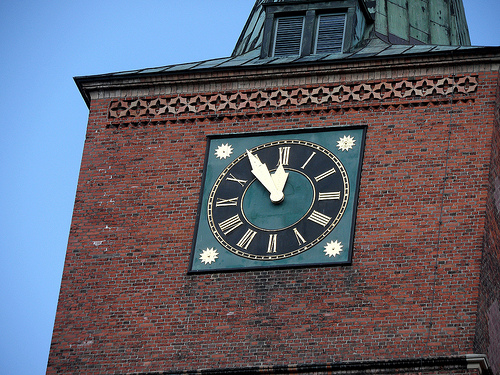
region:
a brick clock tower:
[33, 0, 493, 365]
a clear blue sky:
[1, 0, 54, 313]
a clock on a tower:
[194, 125, 354, 267]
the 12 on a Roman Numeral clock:
[273, 141, 292, 166]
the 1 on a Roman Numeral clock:
[299, 144, 318, 172]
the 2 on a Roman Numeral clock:
[311, 160, 337, 182]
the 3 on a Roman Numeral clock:
[316, 187, 343, 203]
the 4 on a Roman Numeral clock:
[305, 202, 331, 228]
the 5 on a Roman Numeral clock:
[287, 225, 303, 245]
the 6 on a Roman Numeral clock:
[266, 230, 278, 257]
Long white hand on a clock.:
[244, 148, 283, 201]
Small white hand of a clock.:
[268, 161, 290, 202]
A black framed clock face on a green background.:
[187, 122, 370, 275]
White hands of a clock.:
[241, 148, 290, 203]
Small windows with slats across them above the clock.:
[268, 8, 348, 59]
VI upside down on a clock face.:
[265, 233, 277, 254]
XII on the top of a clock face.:
[275, 145, 291, 165]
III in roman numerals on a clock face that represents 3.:
[315, 190, 341, 201]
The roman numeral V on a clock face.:
[291, 226, 306, 246]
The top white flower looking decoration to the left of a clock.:
[213, 143, 234, 158]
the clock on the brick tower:
[207, 139, 351, 260]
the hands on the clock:
[245, 146, 290, 202]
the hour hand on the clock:
[269, 163, 289, 201]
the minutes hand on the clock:
[245, 147, 285, 204]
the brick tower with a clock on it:
[42, 4, 495, 374]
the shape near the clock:
[335, 133, 355, 149]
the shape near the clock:
[322, 238, 342, 255]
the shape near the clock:
[199, 247, 218, 265]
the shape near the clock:
[213, 142, 233, 159]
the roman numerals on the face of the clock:
[214, 146, 340, 253]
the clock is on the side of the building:
[178, 115, 370, 271]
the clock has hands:
[232, 142, 290, 209]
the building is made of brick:
[86, 170, 155, 329]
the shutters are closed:
[260, 9, 347, 59]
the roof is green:
[387, 7, 433, 39]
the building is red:
[217, 289, 323, 342]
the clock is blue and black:
[190, 122, 365, 275]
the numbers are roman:
[306, 142, 346, 233]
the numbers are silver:
[237, 210, 308, 260]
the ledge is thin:
[285, 358, 459, 371]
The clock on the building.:
[185, 123, 378, 273]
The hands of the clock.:
[242, 145, 289, 200]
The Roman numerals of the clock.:
[215, 138, 340, 253]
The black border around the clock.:
[183, 126, 370, 274]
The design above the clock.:
[110, 71, 482, 111]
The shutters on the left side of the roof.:
[270, 10, 304, 52]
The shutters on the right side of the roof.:
[315, 7, 350, 57]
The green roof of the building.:
[70, 0, 498, 72]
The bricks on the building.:
[52, 89, 498, 374]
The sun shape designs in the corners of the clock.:
[194, 133, 355, 266]